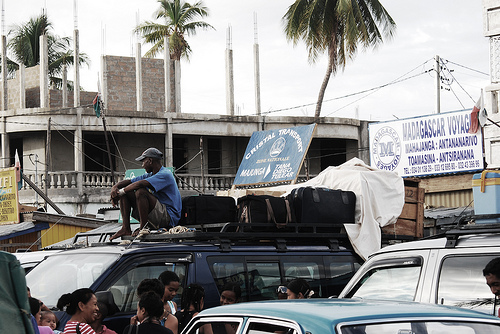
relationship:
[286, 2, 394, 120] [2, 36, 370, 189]
palm tree behind building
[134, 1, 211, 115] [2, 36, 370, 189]
palm tree behind building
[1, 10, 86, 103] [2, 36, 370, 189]
palm tree behind building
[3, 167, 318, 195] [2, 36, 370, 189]
balcony on building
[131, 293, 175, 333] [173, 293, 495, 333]
people between car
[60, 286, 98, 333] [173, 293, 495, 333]
people between car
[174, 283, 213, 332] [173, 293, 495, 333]
people between car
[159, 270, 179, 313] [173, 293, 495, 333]
people between car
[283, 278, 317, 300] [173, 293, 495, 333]
people between car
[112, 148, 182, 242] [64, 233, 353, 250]
man sitting on roof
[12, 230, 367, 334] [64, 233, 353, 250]
car has roof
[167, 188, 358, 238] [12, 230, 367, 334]
luggage on top of car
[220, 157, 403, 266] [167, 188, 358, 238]
sheet covering luggage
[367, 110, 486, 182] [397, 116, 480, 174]
board has letters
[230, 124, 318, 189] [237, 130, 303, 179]
board has letters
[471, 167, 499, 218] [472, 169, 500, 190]
trunk has edges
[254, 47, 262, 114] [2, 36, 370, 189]
pole on top of building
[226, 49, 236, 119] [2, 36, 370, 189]
pole on top of building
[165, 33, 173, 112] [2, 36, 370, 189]
pole on top of building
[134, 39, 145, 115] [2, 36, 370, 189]
pole on top of building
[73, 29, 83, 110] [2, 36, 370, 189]
pole on top of building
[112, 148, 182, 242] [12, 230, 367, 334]
man sitting on car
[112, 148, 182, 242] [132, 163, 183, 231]
man wearing shirt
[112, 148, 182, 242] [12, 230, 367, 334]
man sitting in car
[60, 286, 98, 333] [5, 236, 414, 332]
people standing in street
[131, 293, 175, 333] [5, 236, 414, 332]
people standing in street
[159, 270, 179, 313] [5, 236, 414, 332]
people standing in street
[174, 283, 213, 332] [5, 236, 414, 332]
people standing in street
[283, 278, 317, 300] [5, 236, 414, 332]
people standing in street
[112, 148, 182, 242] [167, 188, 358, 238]
man transporting luggage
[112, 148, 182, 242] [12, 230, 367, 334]
man travelling on top of car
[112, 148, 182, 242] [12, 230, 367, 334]
man waiting on top of car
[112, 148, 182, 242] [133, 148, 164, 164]
man wearing cap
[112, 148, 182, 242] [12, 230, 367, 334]
man sitting on top of car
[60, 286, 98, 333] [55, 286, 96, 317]
people has hair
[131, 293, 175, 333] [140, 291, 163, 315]
people has hair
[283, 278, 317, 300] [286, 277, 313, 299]
people has hair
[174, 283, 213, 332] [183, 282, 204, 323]
people has hair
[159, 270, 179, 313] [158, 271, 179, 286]
people has hair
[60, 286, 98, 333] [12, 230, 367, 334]
people standing next to car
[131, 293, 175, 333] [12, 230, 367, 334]
people standing next to car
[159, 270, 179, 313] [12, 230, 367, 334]
people standing next to car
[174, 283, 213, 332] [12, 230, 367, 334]
people standing next to car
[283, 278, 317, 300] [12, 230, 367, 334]
people standing next to car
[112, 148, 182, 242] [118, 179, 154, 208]
man has knees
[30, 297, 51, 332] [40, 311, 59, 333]
woman holding child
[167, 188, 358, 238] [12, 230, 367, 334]
luggage are on top of car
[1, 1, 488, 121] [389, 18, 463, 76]
sky has a part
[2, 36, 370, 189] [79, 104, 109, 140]
building has a part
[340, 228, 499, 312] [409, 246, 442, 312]
car has a part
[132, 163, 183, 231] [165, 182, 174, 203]
shirt has a part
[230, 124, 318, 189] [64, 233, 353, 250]
board on top of roof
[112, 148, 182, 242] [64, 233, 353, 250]
man on top of roof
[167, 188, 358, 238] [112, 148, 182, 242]
luggage behind man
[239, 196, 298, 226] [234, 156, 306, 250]
bag in middle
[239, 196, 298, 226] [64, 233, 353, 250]
bag in roof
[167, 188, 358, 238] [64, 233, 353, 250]
luggage on top of roof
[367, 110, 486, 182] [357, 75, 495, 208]
board on right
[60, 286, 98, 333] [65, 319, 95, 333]
people wearing shirt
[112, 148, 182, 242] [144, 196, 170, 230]
man wearing short